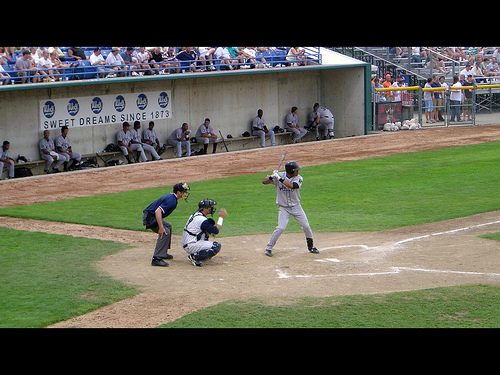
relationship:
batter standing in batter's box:
[262, 159, 321, 259] [263, 240, 398, 283]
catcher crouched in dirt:
[180, 197, 228, 270] [93, 232, 277, 305]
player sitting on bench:
[36, 130, 64, 173] [3, 122, 335, 178]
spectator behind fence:
[446, 74, 464, 124] [373, 80, 499, 129]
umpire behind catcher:
[141, 179, 191, 271] [180, 197, 228, 270]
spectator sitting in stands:
[456, 62, 474, 83] [351, 45, 499, 111]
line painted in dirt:
[269, 265, 399, 280] [93, 232, 277, 305]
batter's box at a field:
[263, 240, 398, 283] [1, 127, 500, 328]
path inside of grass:
[2, 211, 157, 248] [1, 145, 499, 329]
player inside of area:
[36, 130, 64, 173] [0, 63, 367, 183]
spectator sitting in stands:
[446, 74, 464, 124] [351, 45, 499, 111]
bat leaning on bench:
[216, 128, 233, 154] [3, 122, 335, 178]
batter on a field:
[262, 159, 321, 259] [1, 127, 500, 328]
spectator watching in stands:
[446, 74, 464, 124] [351, 45, 499, 111]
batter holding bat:
[262, 159, 321, 259] [269, 150, 288, 180]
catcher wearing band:
[180, 197, 228, 270] [214, 212, 226, 229]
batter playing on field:
[262, 159, 321, 259] [1, 127, 500, 328]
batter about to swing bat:
[262, 159, 321, 259] [269, 150, 288, 180]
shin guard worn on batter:
[305, 233, 317, 254] [262, 159, 321, 259]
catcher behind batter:
[180, 197, 228, 270] [262, 159, 321, 259]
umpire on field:
[141, 179, 191, 271] [1, 127, 500, 328]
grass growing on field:
[1, 145, 499, 329] [1, 127, 500, 328]